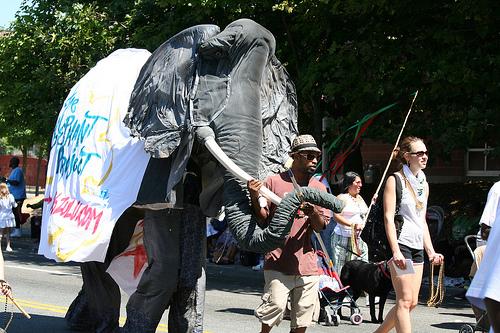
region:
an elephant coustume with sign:
[26, 36, 318, 311]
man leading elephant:
[266, 96, 339, 327]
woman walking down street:
[369, 123, 429, 331]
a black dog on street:
[337, 249, 415, 313]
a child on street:
[0, 173, 12, 257]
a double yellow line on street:
[7, 290, 66, 315]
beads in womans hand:
[422, 246, 450, 313]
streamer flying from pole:
[314, 80, 431, 178]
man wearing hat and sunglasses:
[283, 121, 326, 171]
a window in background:
[442, 138, 492, 177]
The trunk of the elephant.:
[235, 117, 347, 262]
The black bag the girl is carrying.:
[361, 179, 406, 261]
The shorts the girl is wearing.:
[388, 245, 425, 267]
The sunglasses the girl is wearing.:
[415, 147, 428, 156]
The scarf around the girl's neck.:
[397, 165, 426, 196]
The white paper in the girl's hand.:
[393, 260, 413, 276]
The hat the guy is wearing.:
[292, 134, 320, 155]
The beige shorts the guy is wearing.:
[262, 273, 319, 327]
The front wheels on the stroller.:
[329, 309, 362, 326]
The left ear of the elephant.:
[132, 22, 206, 157]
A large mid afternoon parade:
[3, 6, 494, 322]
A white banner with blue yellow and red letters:
[40, 37, 145, 230]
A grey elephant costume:
[152, 31, 297, 195]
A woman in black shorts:
[378, 137, 447, 327]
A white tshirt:
[389, 166, 435, 254]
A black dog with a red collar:
[343, 253, 393, 300]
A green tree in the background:
[11, 6, 95, 71]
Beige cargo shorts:
[260, 268, 330, 331]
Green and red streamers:
[320, 82, 387, 166]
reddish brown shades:
[403, 147, 434, 162]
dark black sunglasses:
[411, 148, 432, 155]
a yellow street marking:
[0, 293, 65, 315]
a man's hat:
[287, 135, 322, 155]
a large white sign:
[35, 47, 155, 269]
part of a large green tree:
[2, 0, 145, 152]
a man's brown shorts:
[254, 266, 326, 331]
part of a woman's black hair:
[335, 172, 360, 190]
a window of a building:
[465, 147, 484, 169]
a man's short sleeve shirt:
[4, 165, 26, 199]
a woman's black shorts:
[384, 242, 429, 264]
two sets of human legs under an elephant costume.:
[36, 17, 341, 329]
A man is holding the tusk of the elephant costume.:
[201, 135, 331, 330]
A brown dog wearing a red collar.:
[337, 255, 390, 322]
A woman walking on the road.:
[375, 130, 445, 330]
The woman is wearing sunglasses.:
[407, 145, 427, 160]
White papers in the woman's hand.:
[387, 251, 413, 273]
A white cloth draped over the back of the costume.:
[35, 50, 150, 260]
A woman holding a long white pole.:
[330, 86, 417, 304]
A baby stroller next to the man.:
[311, 220, 361, 328]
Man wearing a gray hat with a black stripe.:
[285, 133, 326, 157]